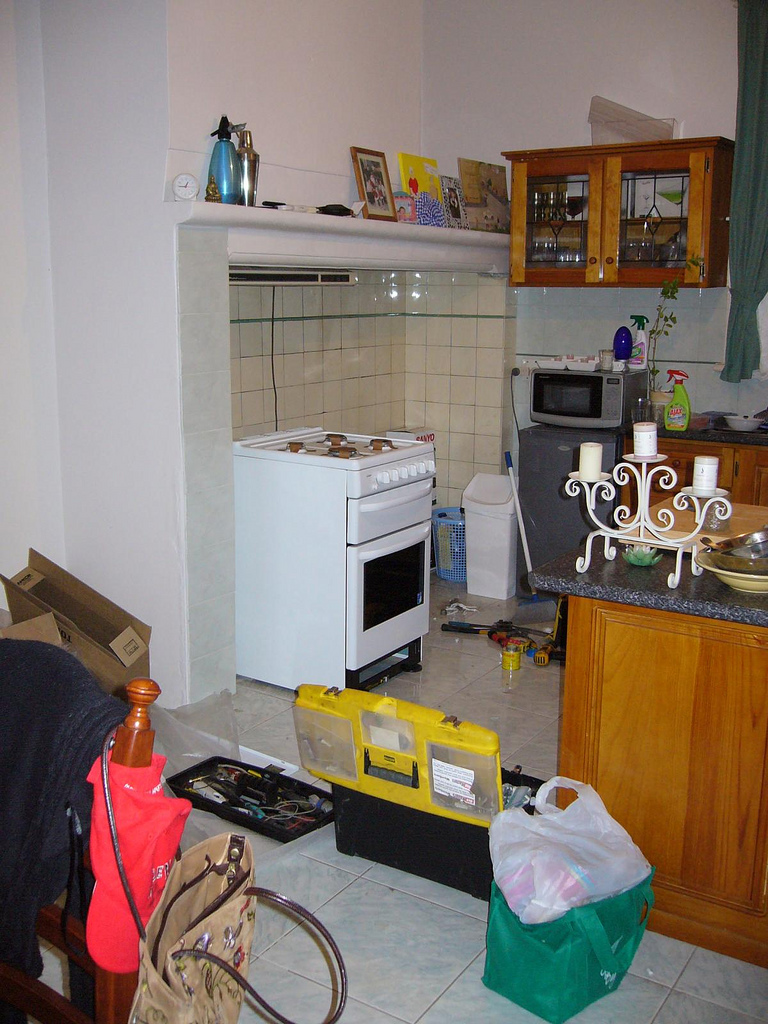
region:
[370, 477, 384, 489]
knob on the stove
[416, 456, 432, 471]
knob on the stove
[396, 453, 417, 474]
knob on the stove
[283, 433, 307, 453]
burner on the stove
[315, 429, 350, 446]
burner on the stove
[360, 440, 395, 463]
burner on the stove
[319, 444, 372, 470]
burner on the stove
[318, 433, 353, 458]
burner on the stove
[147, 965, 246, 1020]
bag on the floor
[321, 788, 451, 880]
box on the floor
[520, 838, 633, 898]
bag in the bag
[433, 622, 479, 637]
tool on the floor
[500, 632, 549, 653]
tool on the floor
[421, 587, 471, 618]
tool on the floor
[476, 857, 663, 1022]
green shopping bag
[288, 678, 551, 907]
yellow and black toolcase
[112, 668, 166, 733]
wooden spoke of chair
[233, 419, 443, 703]
white stove in kitchen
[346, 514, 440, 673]
white oven door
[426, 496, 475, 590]
blue wicker basket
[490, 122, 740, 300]
brown cabinets on wall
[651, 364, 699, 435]
green bottle of spray on counter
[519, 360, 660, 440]
silver microwave on countertop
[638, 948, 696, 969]
tile on the floor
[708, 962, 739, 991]
tile on the floor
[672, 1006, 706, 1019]
tile on the floor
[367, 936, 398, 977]
tile on the floor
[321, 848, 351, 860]
tile on the floor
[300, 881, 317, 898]
tile on the floor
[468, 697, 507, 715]
tile on the floor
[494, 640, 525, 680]
yellow jar on the ground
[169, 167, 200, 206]
white clock on the shelf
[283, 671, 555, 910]
Tool Box on the ground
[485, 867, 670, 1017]
green bag on the ground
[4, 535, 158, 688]
Card board box on the ground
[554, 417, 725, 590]
candle holder on the counter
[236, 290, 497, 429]
tile on the wall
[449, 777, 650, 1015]
bag on the floor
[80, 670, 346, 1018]
bag hooked to chair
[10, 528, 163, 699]
box on the side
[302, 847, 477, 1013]
tile on the floor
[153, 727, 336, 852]
tray on the floor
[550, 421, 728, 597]
a white candle holder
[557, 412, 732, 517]
a set of candles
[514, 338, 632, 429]
microwave on the side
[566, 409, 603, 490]
a candle in the kitchen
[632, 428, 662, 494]
a candle in the kitchen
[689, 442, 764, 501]
a candle in the kitchen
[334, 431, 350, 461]
a burner on the stove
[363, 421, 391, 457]
a burner on the stove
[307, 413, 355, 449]
a burner on the stove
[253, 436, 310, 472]
a burner on the stove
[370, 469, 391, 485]
a knob on the stove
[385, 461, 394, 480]
a knob on the stove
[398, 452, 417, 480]
a knob on the stove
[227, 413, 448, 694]
a stove in center of photo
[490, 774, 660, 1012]
a sack of items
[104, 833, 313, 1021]
a purse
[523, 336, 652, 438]
a microwave on the counter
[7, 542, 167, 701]
an empty box to the left